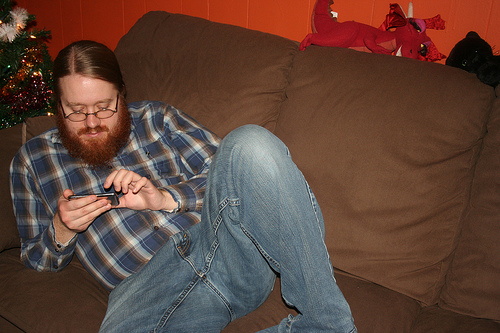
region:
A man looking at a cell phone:
[20, 44, 158, 241]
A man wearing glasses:
[33, 26, 159, 184]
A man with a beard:
[25, 31, 162, 201]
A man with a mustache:
[45, 42, 143, 169]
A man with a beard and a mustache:
[16, 41, 183, 184]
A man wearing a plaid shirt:
[17, 38, 248, 282]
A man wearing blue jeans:
[26, 37, 402, 320]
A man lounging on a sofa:
[18, 8, 438, 323]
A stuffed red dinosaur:
[293, 5, 463, 75]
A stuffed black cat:
[441, 16, 498, 113]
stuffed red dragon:
[275, 0, 480, 67]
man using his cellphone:
[12, 38, 351, 309]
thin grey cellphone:
[60, 185, 132, 224]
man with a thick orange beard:
[31, 31, 159, 181]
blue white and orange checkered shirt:
[8, 95, 252, 310]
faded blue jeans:
[96, 158, 351, 325]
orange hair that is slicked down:
[40, 31, 136, 115]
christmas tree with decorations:
[0, 14, 87, 143]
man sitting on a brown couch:
[34, 20, 473, 319]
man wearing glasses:
[32, 54, 147, 145]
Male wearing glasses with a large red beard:
[42, 40, 149, 171]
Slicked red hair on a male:
[48, 32, 135, 170]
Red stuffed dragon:
[284, 0, 450, 70]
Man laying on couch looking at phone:
[6, 42, 358, 330]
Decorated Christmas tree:
[0, 1, 57, 129]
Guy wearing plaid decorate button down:
[9, 40, 360, 330]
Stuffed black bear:
[442, 23, 499, 96]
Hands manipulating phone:
[51, 165, 171, 231]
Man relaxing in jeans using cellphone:
[8, 33, 364, 331]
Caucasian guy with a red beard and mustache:
[49, 32, 133, 171]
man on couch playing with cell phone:
[24, 27, 345, 304]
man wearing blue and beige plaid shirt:
[12, 131, 193, 268]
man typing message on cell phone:
[48, 166, 168, 232]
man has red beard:
[51, 112, 141, 164]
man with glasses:
[56, 97, 143, 136]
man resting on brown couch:
[123, 46, 418, 274]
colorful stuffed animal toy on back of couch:
[268, 0, 440, 85]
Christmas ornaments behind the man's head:
[3, 6, 59, 121]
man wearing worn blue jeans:
[214, 112, 342, 304]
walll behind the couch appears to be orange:
[151, 0, 291, 55]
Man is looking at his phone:
[42, 86, 150, 220]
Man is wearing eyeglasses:
[56, 93, 130, 131]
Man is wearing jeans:
[83, 120, 368, 332]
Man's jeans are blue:
[91, 114, 368, 331]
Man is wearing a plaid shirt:
[1, 98, 247, 285]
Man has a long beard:
[52, 97, 152, 170]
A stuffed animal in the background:
[290, 3, 452, 78]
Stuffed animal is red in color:
[295, 1, 453, 76]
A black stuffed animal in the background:
[435, 13, 498, 93]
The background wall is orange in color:
[43, 1, 497, 65]